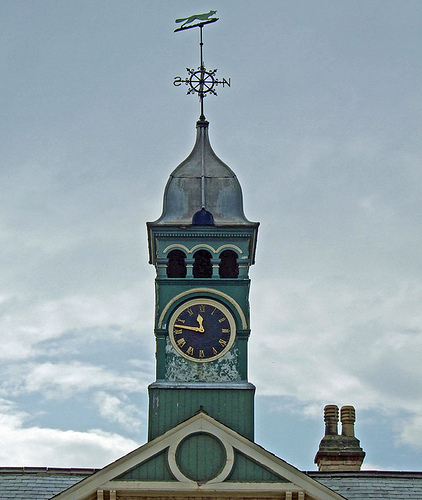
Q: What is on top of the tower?
A: A weather vane.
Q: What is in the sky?
A: Clouds.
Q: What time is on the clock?
A: 11:47.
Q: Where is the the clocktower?
A: The top of the building.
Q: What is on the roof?
A: Shingles.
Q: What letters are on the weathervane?
A: N and S.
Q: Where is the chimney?
A: On the roof.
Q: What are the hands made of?
A: Gold.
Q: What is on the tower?
A: Windows.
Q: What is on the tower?
A: A clock.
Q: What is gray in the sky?
A: Clouds.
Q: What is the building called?
A: Clock tower.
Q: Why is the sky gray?
A: It's cloudy.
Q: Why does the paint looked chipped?
A: Its old.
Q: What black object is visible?
A: Clock.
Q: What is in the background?
A: Another tower.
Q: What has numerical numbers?
A: The clock.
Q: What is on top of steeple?
A: Weather vane.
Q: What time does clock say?
A: 11:47.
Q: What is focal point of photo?
A: The clock.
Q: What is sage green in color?
A: Building.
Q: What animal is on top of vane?
A: A fox.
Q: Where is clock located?
A: At top of tower.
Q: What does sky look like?
A: Cloudy.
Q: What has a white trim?
A: The truss.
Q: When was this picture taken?
A: During the day.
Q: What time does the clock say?
A: Eleven forty five.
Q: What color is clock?
A: Blue.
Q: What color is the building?
A: Green.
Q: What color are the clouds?
A: White.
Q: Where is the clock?
A: On a tower.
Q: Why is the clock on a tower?
A: For people to see.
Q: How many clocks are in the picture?
A: One.